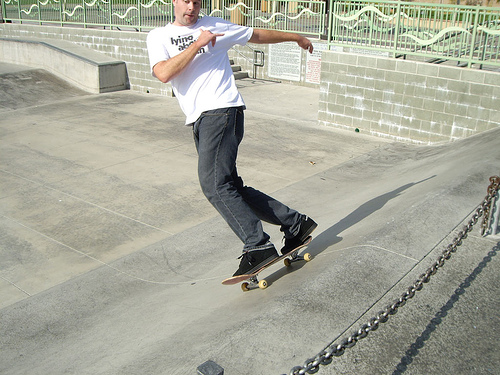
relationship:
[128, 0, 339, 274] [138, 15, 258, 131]
man wearing shirt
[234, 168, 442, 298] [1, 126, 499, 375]
shadow on ground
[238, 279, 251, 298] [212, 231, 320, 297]
wheel on skateboard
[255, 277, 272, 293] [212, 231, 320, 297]
wheel on skateboard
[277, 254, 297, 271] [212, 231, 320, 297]
wheel on skateboard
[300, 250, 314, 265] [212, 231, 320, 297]
wheel on skateboard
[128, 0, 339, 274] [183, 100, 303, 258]
man wearing pants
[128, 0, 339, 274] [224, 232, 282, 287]
man wearing shoe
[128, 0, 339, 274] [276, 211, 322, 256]
man wearing shoe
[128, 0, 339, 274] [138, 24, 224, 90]
man has arm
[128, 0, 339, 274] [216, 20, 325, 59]
man has arm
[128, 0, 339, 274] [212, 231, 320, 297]
man on skateboard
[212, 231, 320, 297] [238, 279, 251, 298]
skateboard has wheel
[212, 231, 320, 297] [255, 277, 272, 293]
skateboard has wheel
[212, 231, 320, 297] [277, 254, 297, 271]
skateboard has wheel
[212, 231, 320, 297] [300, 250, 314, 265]
skateboard has wheel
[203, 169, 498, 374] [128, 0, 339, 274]
chain near man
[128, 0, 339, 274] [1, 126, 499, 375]
man on ramp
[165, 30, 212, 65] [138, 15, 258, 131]
letters on shirt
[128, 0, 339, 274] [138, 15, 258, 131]
man has shirt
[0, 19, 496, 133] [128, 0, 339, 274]
wall behind man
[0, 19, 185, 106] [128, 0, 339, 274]
wall behind man